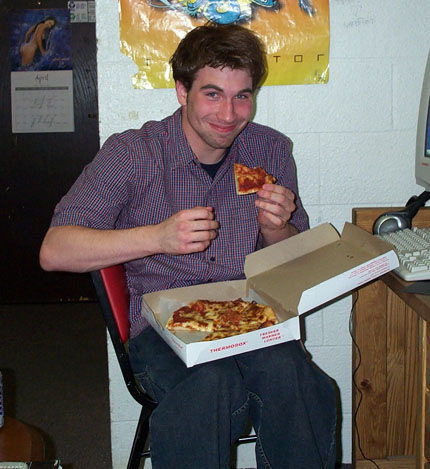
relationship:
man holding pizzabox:
[39, 26, 341, 468] [141, 223, 399, 369]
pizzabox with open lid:
[141, 223, 399, 369] [244, 223, 399, 316]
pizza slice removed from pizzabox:
[234, 162, 278, 197] [141, 223, 399, 369]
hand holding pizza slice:
[254, 184, 295, 227] [234, 162, 278, 197]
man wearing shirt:
[39, 26, 341, 468] [49, 111, 317, 337]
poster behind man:
[119, 0, 330, 88] [39, 26, 341, 468]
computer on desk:
[373, 54, 429, 281] [353, 206, 427, 468]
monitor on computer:
[418, 52, 430, 191] [370, 54, 430, 282]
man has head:
[39, 26, 341, 468] [185, 32, 257, 148]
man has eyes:
[39, 26, 341, 468] [206, 90, 221, 98]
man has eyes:
[39, 26, 341, 468] [237, 94, 249, 100]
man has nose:
[39, 26, 341, 468] [218, 97, 235, 123]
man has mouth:
[39, 26, 341, 468] [210, 123, 237, 131]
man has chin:
[39, 26, 341, 468] [209, 133, 236, 149]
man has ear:
[39, 26, 341, 468] [175, 80, 190, 106]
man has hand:
[39, 26, 341, 468] [254, 184, 295, 227]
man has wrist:
[39, 26, 341, 468] [263, 224, 293, 237]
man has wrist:
[39, 26, 341, 468] [134, 225, 168, 259]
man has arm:
[39, 26, 341, 468] [38, 153, 146, 274]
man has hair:
[39, 26, 341, 468] [171, 27, 265, 93]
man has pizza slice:
[39, 26, 341, 468] [234, 162, 278, 197]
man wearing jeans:
[39, 26, 341, 468] [125, 325, 342, 468]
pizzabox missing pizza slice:
[141, 223, 399, 369] [232, 161, 278, 196]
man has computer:
[39, 26, 341, 468] [370, 54, 430, 282]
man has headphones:
[39, 26, 341, 468] [372, 190, 429, 233]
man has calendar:
[39, 26, 341, 468] [8, 7, 77, 133]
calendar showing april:
[8, 7, 77, 133] [35, 72, 52, 82]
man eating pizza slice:
[39, 26, 341, 468] [234, 162, 278, 197]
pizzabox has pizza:
[141, 223, 399, 369] [168, 300, 278, 341]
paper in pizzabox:
[168, 300, 278, 341] [141, 223, 399, 369]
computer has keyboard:
[370, 54, 430, 282] [376, 228, 427, 281]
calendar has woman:
[8, 7, 77, 133] [18, 18, 56, 67]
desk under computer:
[353, 206, 427, 468] [370, 54, 430, 282]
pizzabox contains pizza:
[141, 223, 399, 369] [168, 300, 278, 341]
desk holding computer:
[353, 206, 427, 468] [370, 54, 430, 282]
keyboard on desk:
[376, 228, 427, 281] [353, 206, 427, 468]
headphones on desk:
[372, 190, 429, 233] [353, 206, 427, 468]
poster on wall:
[119, 0, 330, 88] [39, 26, 341, 468]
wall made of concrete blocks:
[39, 26, 341, 468] [324, 142, 381, 183]